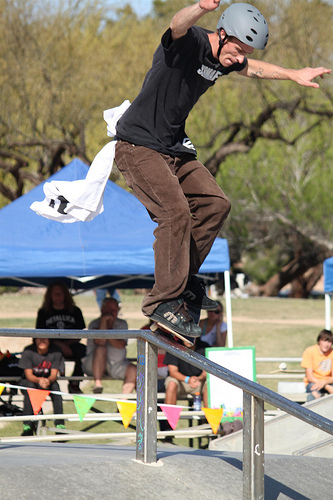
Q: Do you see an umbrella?
A: No, there are no umbrellas.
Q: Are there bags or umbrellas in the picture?
A: No, there are no umbrellas or bags.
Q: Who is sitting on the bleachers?
A: The people are sitting on the bleachers.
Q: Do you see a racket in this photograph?
A: No, there are no rackets.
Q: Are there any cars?
A: No, there are no cars.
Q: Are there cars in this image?
A: No, there are no cars.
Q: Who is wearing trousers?
A: The boy is wearing trousers.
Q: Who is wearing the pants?
A: The boy is wearing trousers.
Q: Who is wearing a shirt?
A: The boy is wearing a shirt.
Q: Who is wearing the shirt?
A: The boy is wearing a shirt.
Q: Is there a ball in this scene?
A: No, there are no balls.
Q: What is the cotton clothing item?
A: The clothing item is a t-shirt.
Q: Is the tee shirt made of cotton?
A: Yes, the tee shirt is made of cotton.